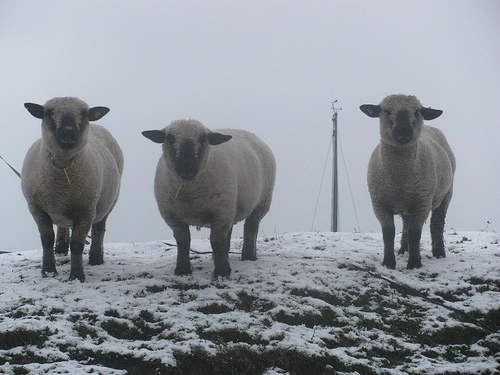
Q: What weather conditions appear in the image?
A: It is foggy.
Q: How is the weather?
A: It is foggy.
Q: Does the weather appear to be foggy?
A: Yes, it is foggy.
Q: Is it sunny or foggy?
A: It is foggy.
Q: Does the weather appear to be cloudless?
A: No, it is foggy.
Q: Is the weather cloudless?
A: No, it is foggy.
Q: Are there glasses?
A: No, there are no glasses.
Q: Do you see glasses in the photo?
A: No, there are no glasses.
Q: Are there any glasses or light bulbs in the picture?
A: No, there are no glasses or light bulbs.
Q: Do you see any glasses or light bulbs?
A: No, there are no glasses or light bulbs.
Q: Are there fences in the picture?
A: No, there are no fences.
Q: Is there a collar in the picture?
A: Yes, there is a collar.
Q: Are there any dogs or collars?
A: Yes, there is a collar.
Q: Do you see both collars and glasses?
A: No, there is a collar but no glasses.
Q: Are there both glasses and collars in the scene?
A: No, there is a collar but no glasses.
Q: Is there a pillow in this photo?
A: No, there are no pillows.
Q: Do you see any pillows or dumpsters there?
A: No, there are no pillows or dumpsters.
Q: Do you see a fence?
A: No, there are no fences.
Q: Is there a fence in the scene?
A: No, there are no fences.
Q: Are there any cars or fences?
A: No, there are no fences or cars.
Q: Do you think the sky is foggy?
A: Yes, the sky is foggy.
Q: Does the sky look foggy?
A: Yes, the sky is foggy.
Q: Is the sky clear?
A: No, the sky is foggy.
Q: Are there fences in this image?
A: No, there are no fences.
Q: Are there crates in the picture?
A: No, there are no crates.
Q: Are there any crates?
A: No, there are no crates.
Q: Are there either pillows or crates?
A: No, there are no crates or pillows.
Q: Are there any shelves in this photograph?
A: No, there are no shelves.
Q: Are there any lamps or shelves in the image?
A: No, there are no shelves or lamps.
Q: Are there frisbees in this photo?
A: No, there are no frisbees.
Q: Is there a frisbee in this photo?
A: No, there are no frisbees.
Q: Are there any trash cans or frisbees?
A: No, there are no frisbees or trash cans.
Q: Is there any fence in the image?
A: No, there are no fences.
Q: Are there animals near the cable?
A: Yes, there is an animal near the cable.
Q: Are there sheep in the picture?
A: Yes, there is a sheep.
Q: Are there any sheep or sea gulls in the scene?
A: Yes, there is a sheep.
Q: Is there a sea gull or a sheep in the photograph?
A: Yes, there is a sheep.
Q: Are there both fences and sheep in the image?
A: No, there is a sheep but no fences.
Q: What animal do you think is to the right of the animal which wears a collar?
A: The animal is a sheep.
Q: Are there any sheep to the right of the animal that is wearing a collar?
A: Yes, there is a sheep to the right of the animal.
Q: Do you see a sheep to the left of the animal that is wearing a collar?
A: No, the sheep is to the right of the animal.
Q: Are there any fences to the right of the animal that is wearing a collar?
A: No, there is a sheep to the right of the animal.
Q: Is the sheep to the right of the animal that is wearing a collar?
A: Yes, the sheep is to the right of the animal.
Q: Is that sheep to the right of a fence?
A: No, the sheep is to the right of the animal.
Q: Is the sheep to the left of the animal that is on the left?
A: No, the sheep is to the right of the animal.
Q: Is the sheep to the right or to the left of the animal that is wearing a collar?
A: The sheep is to the right of the animal.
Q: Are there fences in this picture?
A: No, there are no fences.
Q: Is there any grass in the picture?
A: Yes, there is grass.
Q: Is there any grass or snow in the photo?
A: Yes, there is grass.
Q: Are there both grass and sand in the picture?
A: No, there is grass but no sand.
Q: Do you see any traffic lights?
A: No, there are no traffic lights.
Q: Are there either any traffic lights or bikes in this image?
A: No, there are no traffic lights or bikes.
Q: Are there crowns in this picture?
A: No, there are no crowns.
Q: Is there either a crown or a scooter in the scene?
A: No, there are no crowns or scooters.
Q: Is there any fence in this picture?
A: No, there are no fences.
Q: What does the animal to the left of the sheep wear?
A: The animal wears a collar.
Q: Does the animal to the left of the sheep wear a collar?
A: Yes, the animal wears a collar.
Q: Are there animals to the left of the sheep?
A: Yes, there is an animal to the left of the sheep.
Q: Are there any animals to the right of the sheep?
A: No, the animal is to the left of the sheep.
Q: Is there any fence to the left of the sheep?
A: No, there is an animal to the left of the sheep.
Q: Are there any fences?
A: No, there are no fences.